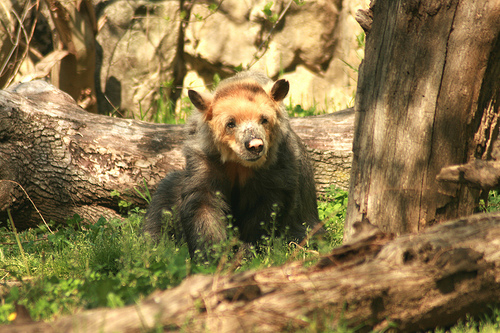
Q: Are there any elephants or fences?
A: No, there are no fences or elephants.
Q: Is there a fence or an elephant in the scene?
A: No, there are no fences or elephants.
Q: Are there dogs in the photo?
A: No, there are no dogs.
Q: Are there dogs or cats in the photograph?
A: No, there are no dogs or cats.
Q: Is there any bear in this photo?
A: Yes, there is a bear.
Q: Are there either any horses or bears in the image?
A: Yes, there is a bear.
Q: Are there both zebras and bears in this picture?
A: No, there is a bear but no zebras.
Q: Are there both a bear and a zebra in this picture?
A: No, there is a bear but no zebras.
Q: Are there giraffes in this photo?
A: No, there are no giraffes.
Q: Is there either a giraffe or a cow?
A: No, there are no giraffes or cows.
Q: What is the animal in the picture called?
A: The animal is a bear.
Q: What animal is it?
A: The animal is a bear.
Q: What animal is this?
A: That is a bear.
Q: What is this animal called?
A: That is a bear.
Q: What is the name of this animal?
A: That is a bear.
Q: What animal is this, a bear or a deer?
A: That is a bear.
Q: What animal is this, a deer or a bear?
A: That is a bear.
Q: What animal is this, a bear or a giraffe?
A: This is a bear.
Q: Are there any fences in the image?
A: No, there are no fences.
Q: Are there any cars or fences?
A: No, there are no fences or cars.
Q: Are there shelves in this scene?
A: No, there are no shelves.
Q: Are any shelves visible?
A: No, there are no shelves.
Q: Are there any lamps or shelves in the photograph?
A: No, there are no shelves or lamps.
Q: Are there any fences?
A: No, there are no fences.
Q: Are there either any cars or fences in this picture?
A: No, there are no fences or cars.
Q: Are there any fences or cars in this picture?
A: No, there are no fences or cars.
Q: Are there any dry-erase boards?
A: No, there are no dry-erase boards.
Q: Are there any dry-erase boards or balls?
A: No, there are no dry-erase boards or balls.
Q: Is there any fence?
A: No, there are no fences.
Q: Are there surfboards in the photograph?
A: No, there are no surfboards.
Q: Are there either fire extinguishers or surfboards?
A: No, there are no surfboards or fire extinguishers.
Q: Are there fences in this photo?
A: No, there are no fences.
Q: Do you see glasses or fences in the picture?
A: No, there are no fences or glasses.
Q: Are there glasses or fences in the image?
A: No, there are no fences or glasses.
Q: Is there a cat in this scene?
A: No, there are no cats.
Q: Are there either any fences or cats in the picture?
A: No, there are no cats or fences.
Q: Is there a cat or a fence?
A: No, there are no cats or fences.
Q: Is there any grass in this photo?
A: Yes, there is grass.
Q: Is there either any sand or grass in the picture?
A: Yes, there is grass.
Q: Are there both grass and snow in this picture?
A: No, there is grass but no snow.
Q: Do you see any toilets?
A: No, there are no toilets.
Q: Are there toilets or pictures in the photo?
A: No, there are no toilets or pictures.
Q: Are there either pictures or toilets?
A: No, there are no toilets or pictures.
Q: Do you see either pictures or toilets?
A: No, there are no toilets or pictures.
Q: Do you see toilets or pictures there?
A: No, there are no toilets or pictures.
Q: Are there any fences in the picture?
A: No, there are no fences.